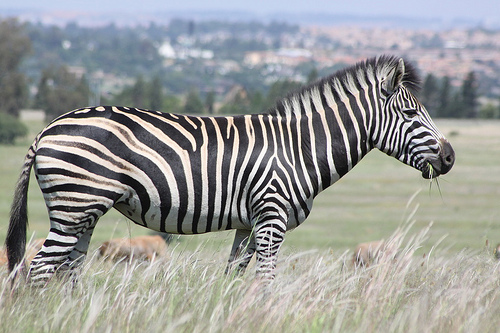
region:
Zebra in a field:
[13, 41, 490, 248]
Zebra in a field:
[135, 75, 452, 218]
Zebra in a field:
[25, 175, 377, 287]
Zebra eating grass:
[414, 146, 471, 183]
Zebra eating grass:
[403, 126, 458, 191]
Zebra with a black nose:
[398, 141, 455, 191]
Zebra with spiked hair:
[272, 44, 421, 121]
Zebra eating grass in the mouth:
[405, 156, 460, 211]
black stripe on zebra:
[366, 86, 376, 146]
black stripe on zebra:
[358, 88, 370, 125]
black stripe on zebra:
[348, 92, 368, 156]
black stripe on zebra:
[335, 98, 361, 168]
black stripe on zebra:
[323, 105, 349, 175]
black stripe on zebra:
[310, 113, 334, 188]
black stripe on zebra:
[298, 114, 319, 196]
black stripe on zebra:
[287, 110, 308, 195]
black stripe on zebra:
[275, 113, 291, 159]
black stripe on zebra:
[271, 115, 311, 217]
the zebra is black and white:
[42, 60, 410, 203]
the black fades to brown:
[67, 165, 271, 251]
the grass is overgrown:
[125, 256, 332, 331]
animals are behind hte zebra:
[97, 230, 198, 277]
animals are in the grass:
[342, 224, 449, 286]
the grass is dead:
[270, 254, 462, 300]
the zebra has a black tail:
[11, 189, 78, 261]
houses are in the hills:
[137, 28, 331, 82]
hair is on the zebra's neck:
[263, 59, 438, 100]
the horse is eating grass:
[402, 123, 455, 190]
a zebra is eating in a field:
[8, 52, 455, 289]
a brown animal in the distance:
[96, 233, 183, 260]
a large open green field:
[0, 113, 497, 255]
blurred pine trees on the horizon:
[2, 60, 499, 117]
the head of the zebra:
[368, 57, 457, 180]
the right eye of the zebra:
[403, 108, 424, 120]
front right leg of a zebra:
[252, 193, 291, 285]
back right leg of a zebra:
[18, 156, 108, 301]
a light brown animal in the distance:
[348, 238, 394, 271]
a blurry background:
[9, 8, 493, 256]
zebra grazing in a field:
[7, 53, 454, 301]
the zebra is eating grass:
[4, 51, 459, 303]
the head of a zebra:
[369, 55, 453, 175]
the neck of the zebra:
[289, 68, 373, 191]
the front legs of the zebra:
[222, 208, 291, 286]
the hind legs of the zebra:
[19, 112, 112, 295]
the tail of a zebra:
[2, 126, 44, 274]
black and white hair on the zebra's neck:
[268, 43, 415, 116]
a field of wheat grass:
[4, 229, 497, 331]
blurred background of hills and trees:
[2, 17, 498, 128]